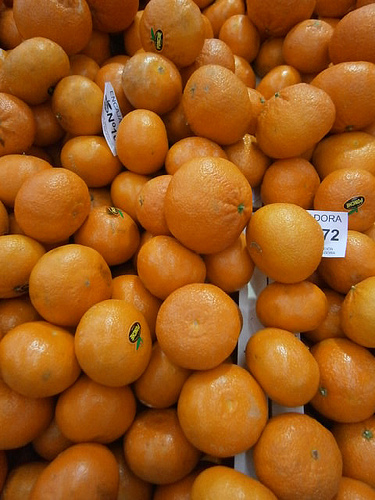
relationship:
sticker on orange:
[153, 30, 164, 53] [140, 1, 204, 69]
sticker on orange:
[344, 195, 365, 210] [314, 167, 375, 232]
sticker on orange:
[128, 320, 142, 343] [74, 298, 152, 387]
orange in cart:
[140, 1, 204, 69] [1, 1, 374, 500]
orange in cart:
[13, 167, 91, 240] [1, 1, 374, 500]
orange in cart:
[166, 157, 253, 254] [1, 1, 374, 500]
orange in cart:
[314, 167, 375, 232] [1, 1, 374, 500]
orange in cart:
[74, 298, 152, 387] [1, 1, 374, 500]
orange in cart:
[182, 64, 250, 147] [1, 1, 374, 500]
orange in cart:
[255, 83, 335, 158] [1, 1, 374, 500]